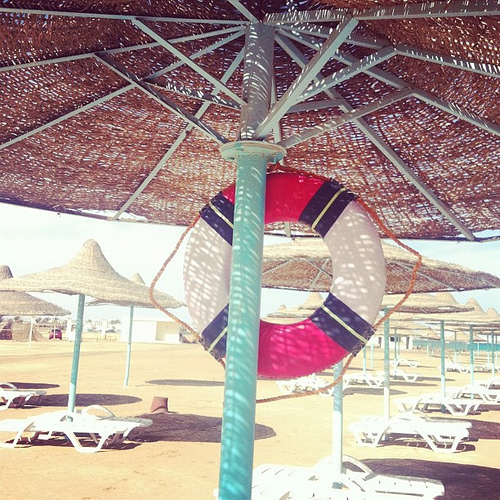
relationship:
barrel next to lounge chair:
[146, 391, 171, 413] [4, 374, 151, 456]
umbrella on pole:
[0, 239, 182, 442] [123, 305, 134, 385]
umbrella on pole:
[261, 235, 499, 488] [331, 357, 346, 474]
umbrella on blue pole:
[261, 235, 499, 488] [436, 320, 446, 380]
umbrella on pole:
[261, 235, 499, 488] [382, 310, 389, 430]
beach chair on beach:
[212, 472, 445, 498] [25, 130, 499, 483]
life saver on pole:
[150, 168, 423, 405] [214, 25, 265, 498]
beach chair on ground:
[347, 411, 474, 451] [0, 330, 500, 497]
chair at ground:
[398, 389, 498, 419] [0, 330, 500, 497]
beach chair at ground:
[212, 472, 445, 498] [0, 330, 500, 497]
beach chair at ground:
[0, 387, 30, 410] [0, 330, 500, 497]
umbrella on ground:
[7, 239, 181, 310] [0, 330, 500, 497]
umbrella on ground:
[4, 6, 497, 236] [0, 330, 500, 497]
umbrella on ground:
[224, 241, 499, 290] [0, 330, 500, 497]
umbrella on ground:
[261, 235, 499, 488] [0, 330, 500, 497]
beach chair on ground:
[347, 409, 474, 456] [0, 330, 500, 497]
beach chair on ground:
[252, 462, 447, 497] [0, 330, 500, 497]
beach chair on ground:
[2, 412, 148, 451] [0, 330, 500, 497]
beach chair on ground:
[0, 387, 38, 406] [0, 330, 500, 497]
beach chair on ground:
[212, 472, 445, 498] [0, 330, 500, 497]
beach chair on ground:
[0, 410, 143, 454] [0, 330, 500, 497]